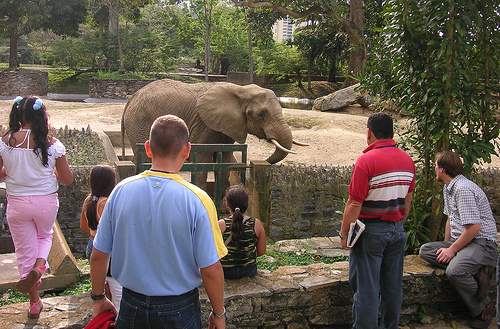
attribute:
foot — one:
[14, 260, 43, 317]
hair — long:
[230, 207, 250, 259]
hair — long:
[83, 175, 111, 231]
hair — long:
[13, 93, 46, 163]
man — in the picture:
[329, 110, 413, 327]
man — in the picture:
[326, 109, 425, 310]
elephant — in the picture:
[114, 73, 307, 184]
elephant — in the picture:
[107, 76, 302, 191]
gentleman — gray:
[420, 144, 499, 320]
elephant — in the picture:
[119, 74, 294, 174]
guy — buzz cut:
[93, 99, 253, 272]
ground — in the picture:
[208, 61, 236, 89]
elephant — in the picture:
[119, 77, 309, 212]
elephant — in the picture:
[116, 77, 313, 196]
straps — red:
[82, 306, 120, 326]